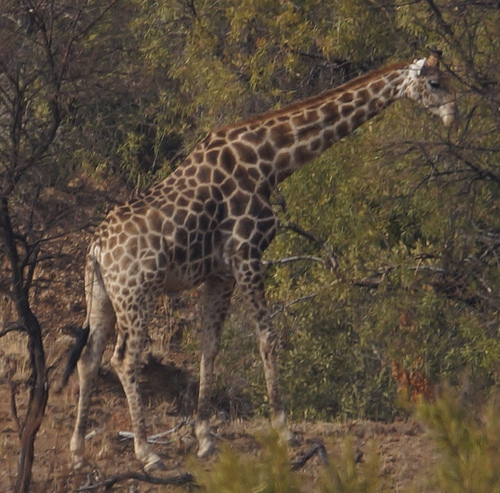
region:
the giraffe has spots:
[53, 69, 493, 414]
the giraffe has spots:
[88, 44, 449, 283]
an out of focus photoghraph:
[19, 41, 489, 486]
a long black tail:
[52, 307, 104, 384]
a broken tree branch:
[73, 442, 353, 490]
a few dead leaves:
[388, 336, 445, 431]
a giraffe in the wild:
[48, 25, 468, 485]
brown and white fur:
[98, 203, 218, 258]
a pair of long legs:
[191, 265, 339, 468]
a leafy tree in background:
[99, 19, 479, 285]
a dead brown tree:
[5, 0, 114, 475]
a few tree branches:
[286, 216, 350, 310]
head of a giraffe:
[392, 45, 470, 141]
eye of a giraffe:
[420, 73, 449, 94]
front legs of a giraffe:
[181, 281, 309, 467]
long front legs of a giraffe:
[179, 296, 312, 457]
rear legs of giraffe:
[67, 301, 169, 480]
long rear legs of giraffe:
[57, 302, 172, 479]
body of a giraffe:
[81, 155, 281, 282]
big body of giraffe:
[93, 184, 272, 292]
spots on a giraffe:
[114, 206, 260, 261]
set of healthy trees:
[328, 276, 464, 389]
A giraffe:
[191, 138, 319, 347]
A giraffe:
[121, 216, 217, 330]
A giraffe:
[100, 159, 191, 349]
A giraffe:
[108, 232, 271, 429]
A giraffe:
[113, 117, 238, 330]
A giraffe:
[183, 207, 289, 426]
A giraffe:
[183, 230, 229, 373]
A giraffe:
[163, 153, 231, 315]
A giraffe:
[147, 178, 227, 272]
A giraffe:
[85, 160, 228, 407]